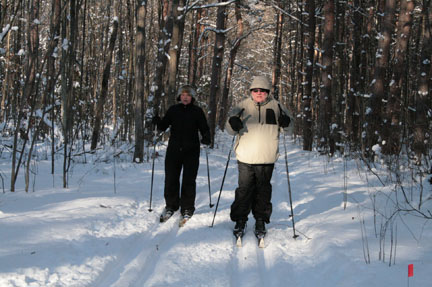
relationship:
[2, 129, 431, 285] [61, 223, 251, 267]
snow on ground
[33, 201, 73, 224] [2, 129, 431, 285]
snow covering ground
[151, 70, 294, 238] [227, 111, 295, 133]
people wearing gloves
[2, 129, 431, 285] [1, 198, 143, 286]
snow clean and white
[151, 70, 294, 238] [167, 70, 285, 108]
people wearing hats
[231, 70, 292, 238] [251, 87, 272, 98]
person wearing sunglasses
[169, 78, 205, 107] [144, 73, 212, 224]
head of person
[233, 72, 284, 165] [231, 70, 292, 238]
jacket on person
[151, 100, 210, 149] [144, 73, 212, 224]
jacket black on person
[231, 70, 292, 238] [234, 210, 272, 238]
person wears ski boots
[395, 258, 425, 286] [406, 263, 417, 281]
flag colored red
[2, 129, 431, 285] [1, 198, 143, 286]
snow still white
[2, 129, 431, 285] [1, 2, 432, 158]
snow covers trees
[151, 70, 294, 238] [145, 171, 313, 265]
people together skiing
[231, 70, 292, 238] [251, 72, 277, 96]
person wearing a hat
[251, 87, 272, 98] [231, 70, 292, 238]
sunglasses on a person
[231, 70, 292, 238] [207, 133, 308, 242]
person holding ski poles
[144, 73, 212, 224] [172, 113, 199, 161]
person wearing all black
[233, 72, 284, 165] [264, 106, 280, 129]
jacket has a pocket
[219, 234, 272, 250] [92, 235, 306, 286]
skis following in paths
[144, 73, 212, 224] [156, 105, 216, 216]
person in black snow suit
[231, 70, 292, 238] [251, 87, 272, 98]
person has on sunglasses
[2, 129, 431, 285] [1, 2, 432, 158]
snow all through trees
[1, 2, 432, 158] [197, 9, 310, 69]
trees show some sunshine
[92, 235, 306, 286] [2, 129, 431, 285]
paths in snow